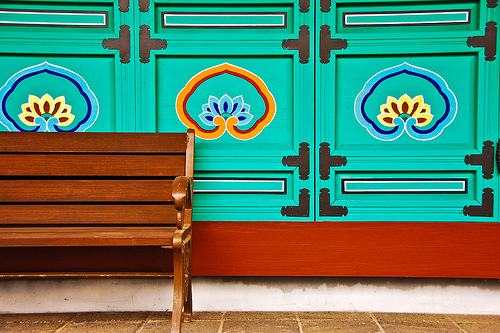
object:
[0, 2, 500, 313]
wall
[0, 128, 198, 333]
bench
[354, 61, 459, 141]
design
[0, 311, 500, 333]
floor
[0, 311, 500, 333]
tile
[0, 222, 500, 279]
base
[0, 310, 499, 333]
pavement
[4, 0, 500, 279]
door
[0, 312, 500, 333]
grout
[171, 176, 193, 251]
arm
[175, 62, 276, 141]
design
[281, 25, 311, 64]
inlay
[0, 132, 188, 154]
slat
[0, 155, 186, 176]
slat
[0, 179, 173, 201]
slat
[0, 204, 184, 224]
slat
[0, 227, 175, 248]
slat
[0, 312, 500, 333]
sidewalk